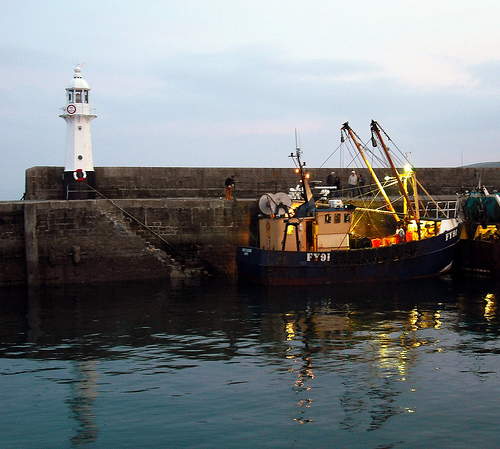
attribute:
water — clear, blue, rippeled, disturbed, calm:
[1, 284, 492, 449]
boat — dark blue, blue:
[238, 123, 463, 285]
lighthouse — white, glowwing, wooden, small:
[59, 60, 98, 200]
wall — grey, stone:
[1, 166, 238, 283]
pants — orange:
[225, 186, 232, 201]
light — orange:
[294, 166, 299, 175]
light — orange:
[305, 171, 310, 180]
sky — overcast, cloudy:
[3, 1, 499, 166]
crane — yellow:
[344, 122, 400, 223]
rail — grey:
[88, 186, 178, 252]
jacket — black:
[223, 176, 235, 188]